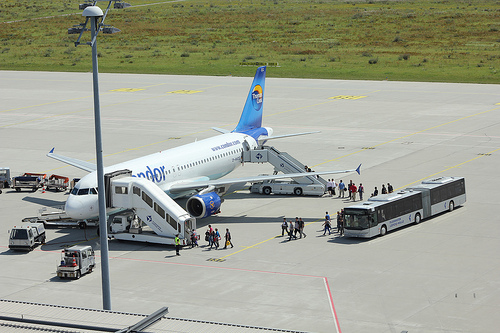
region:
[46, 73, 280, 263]
Jet preparing for take off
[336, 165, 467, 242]
Double long airport tram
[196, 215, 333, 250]
Passengers boarding plane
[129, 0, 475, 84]
Grass area by runway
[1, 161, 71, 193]
Baggage carts for luggage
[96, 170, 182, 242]
Detachable stairs for boarding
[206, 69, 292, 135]
Blue tail wing of jet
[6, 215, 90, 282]
Airport maintenance vehicles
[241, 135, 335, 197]
Open detachable set of steps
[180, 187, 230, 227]
Blue jet engine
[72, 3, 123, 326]
big light post on the left hand side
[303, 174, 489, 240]
large bus on the right hand side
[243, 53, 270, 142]
blue tail of the plane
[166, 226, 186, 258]
plane director in lime green vest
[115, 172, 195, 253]
stairs at the front end of the plane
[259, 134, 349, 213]
stairs at the back of the plane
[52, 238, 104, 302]
mini truck closest to the light pole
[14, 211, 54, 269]
mini truck farthest from the light pole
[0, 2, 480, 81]
green field behind the plane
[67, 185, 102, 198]
pilot windows at the front of the plane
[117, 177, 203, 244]
a white covered stairway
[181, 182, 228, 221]
a dark blue engine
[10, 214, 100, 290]
a few grey vehicles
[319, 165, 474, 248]
a long grey bus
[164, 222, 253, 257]
a group of people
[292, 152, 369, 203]
a few people boarding a plane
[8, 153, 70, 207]
a colorful luggage carrier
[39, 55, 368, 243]
a blue and white plane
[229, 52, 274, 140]
a bright blue plane tail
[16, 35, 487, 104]
a field near the tarmac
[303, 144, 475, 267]
bus on the taramac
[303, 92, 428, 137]
runway for the plane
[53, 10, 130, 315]
light pole for the runway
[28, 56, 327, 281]
plane on the runway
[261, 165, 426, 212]
people on the runway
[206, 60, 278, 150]
tail of the plane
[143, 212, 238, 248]
people going into plane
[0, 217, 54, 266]
truck on the taramac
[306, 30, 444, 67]
field behind the runway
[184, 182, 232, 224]
engine of the plane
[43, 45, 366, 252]
An airplane is parked at an airport.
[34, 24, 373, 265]
The colors of an airplane are blue, white, and yellow.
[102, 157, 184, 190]
An airplane has writing on it's side.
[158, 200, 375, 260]
People are boarding the front of an aircraft.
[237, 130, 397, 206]
People are boarding the rear of an aircraft.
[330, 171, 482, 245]
A bus is parked near an aircraft.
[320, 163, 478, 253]
The colors of a bus are gray and black.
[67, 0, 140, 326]
A tall object is in front of an aircraft.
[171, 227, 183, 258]
A person in a lime-green top is standing near the front of an airplane.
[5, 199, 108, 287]
Service vehicles are parked in front of an airplane.